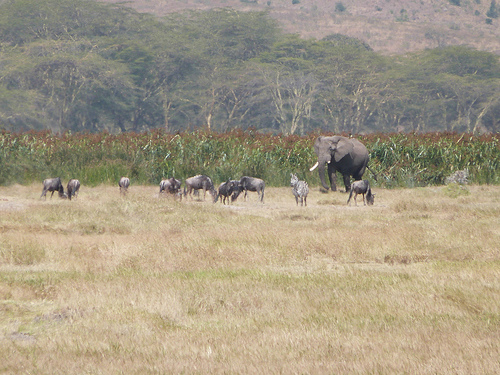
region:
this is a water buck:
[39, 168, 64, 204]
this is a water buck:
[64, 168, 85, 200]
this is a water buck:
[149, 175, 170, 197]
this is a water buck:
[108, 162, 139, 192]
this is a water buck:
[152, 172, 183, 198]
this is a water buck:
[180, 158, 221, 214]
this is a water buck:
[210, 170, 241, 206]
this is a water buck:
[231, 161, 276, 209]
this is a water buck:
[343, 172, 383, 208]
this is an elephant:
[293, 116, 380, 208]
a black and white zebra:
[286, 170, 315, 207]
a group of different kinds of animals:
[38, 133, 378, 206]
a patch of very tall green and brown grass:
[0, 124, 298, 169]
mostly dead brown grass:
[1, 208, 498, 373]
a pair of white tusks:
[308, 158, 333, 170]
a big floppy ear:
[333, 139, 353, 164]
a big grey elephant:
[308, 133, 370, 193]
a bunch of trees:
[2, 0, 499, 135]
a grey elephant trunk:
[316, 158, 329, 188]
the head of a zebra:
[288, 172, 298, 191]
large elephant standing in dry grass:
[313, 139, 369, 226]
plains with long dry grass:
[179, 275, 324, 335]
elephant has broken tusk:
[309, 158, 343, 186]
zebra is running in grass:
[281, 160, 309, 218]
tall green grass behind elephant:
[382, 148, 419, 189]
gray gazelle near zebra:
[221, 171, 251, 212]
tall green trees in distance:
[123, 69, 186, 131]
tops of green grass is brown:
[151, 128, 217, 155]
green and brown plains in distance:
[381, 14, 450, 54]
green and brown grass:
[306, 288, 361, 337]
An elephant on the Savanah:
[305, 128, 377, 200]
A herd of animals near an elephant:
[30, 167, 412, 209]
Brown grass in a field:
[19, 238, 452, 367]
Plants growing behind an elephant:
[13, 121, 498, 170]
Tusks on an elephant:
[310, 152, 333, 177]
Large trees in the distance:
[8, 7, 497, 137]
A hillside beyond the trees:
[138, 2, 499, 87]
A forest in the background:
[6, 17, 488, 131]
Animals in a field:
[19, 103, 495, 222]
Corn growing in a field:
[18, 99, 277, 188]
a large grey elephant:
[308, 133, 377, 195]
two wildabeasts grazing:
[37, 176, 80, 202]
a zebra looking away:
[287, 171, 309, 207]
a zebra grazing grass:
[343, 178, 377, 206]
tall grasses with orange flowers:
[1, 126, 498, 191]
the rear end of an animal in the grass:
[114, 174, 131, 195]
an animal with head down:
[182, 173, 217, 205]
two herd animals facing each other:
[215, 174, 267, 205]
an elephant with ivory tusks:
[306, 133, 373, 195]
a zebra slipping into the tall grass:
[447, 165, 468, 185]